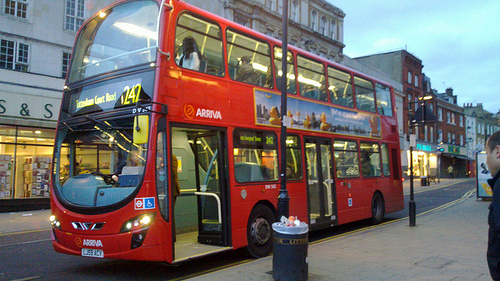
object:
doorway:
[164, 126, 226, 249]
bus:
[50, 0, 408, 265]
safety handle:
[196, 189, 227, 223]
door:
[173, 131, 226, 258]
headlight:
[125, 213, 153, 238]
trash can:
[274, 214, 313, 280]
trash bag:
[277, 215, 307, 238]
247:
[123, 84, 143, 106]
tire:
[244, 209, 284, 259]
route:
[71, 93, 121, 108]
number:
[122, 84, 147, 107]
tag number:
[81, 249, 105, 260]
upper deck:
[170, 25, 392, 113]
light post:
[407, 129, 417, 226]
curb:
[175, 191, 500, 281]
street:
[0, 179, 476, 281]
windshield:
[54, 115, 147, 187]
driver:
[130, 148, 147, 179]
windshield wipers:
[52, 118, 147, 162]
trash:
[281, 214, 303, 226]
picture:
[251, 91, 385, 139]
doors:
[304, 140, 335, 220]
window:
[235, 125, 277, 184]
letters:
[196, 106, 231, 124]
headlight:
[49, 213, 64, 231]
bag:
[281, 222, 305, 237]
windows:
[226, 27, 274, 87]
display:
[62, 79, 154, 114]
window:
[64, 0, 166, 77]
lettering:
[70, 96, 118, 107]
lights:
[68, 80, 148, 108]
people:
[182, 35, 200, 69]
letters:
[1, 98, 56, 119]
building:
[0, 0, 344, 210]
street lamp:
[406, 130, 419, 227]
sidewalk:
[173, 182, 499, 281]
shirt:
[182, 54, 212, 77]